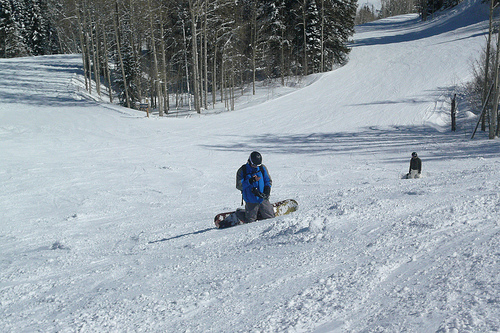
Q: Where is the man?
A: On the mountain.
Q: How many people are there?
A: Two.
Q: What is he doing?
A: Kneeling.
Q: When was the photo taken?
A: During the day.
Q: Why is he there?
A: He was snowboarding.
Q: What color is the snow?
A: White.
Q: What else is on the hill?
A: Trees.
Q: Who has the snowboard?
A: A man.